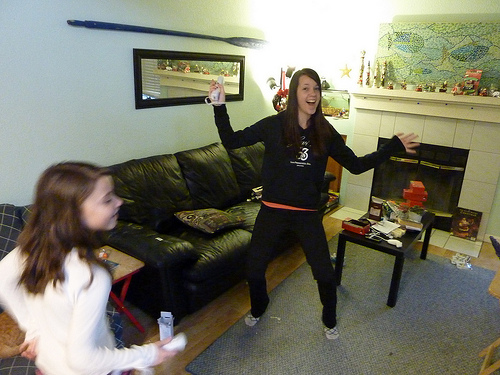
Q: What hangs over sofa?
A: A black framed mirror.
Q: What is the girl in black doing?
A: Dancing.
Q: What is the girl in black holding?
A: Wii remote control.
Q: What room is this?
A: Living room.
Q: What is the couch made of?
A: Leather.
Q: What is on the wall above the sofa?
A: Mirror.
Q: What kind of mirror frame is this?
A: Black mirror frame.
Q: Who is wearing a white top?
A: The younger girl.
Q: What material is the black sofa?
A: Leather.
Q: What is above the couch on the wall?
A: Mirror.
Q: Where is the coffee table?
A: Behind the older woman.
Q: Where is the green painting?
A: Over the fireplace.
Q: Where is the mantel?
A: Over fireplace.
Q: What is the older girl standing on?
A: Rug.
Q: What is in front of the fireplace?
A: Coffee table.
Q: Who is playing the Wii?
A: Both girls.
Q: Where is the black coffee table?
A: Behind the dancing girl.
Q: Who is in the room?
A: Two girls.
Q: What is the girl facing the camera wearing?
A: Black shirt and pants.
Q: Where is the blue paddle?
A: Mounted on the wall.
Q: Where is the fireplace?
A: Behind the girl in black.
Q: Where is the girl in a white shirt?
A: On the left.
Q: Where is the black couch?
A: Left from the dancing girl.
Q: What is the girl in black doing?
A: Dancing.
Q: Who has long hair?
A: Both girls.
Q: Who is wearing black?
A: The girl who is dancing.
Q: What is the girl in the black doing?
A: Dancing.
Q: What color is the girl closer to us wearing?
A: White.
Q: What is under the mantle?
A: Fireplace.